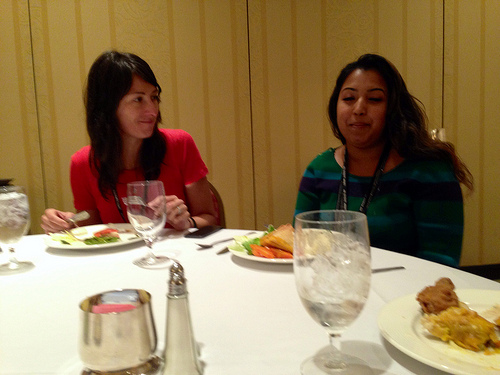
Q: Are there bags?
A: No, there are no bags.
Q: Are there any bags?
A: No, there are no bags.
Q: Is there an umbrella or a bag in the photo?
A: No, there are no bags or umbrellas.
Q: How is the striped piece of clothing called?
A: The clothing item is a blouse.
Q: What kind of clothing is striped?
A: The clothing is a blouse.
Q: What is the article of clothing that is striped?
A: The clothing item is a blouse.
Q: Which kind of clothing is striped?
A: The clothing is a blouse.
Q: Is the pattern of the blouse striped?
A: Yes, the blouse is striped.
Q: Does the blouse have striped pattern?
A: Yes, the blouse is striped.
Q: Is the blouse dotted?
A: No, the blouse is striped.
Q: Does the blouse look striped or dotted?
A: The blouse is striped.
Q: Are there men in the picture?
A: No, there are no men.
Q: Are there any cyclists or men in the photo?
A: No, there are no men or cyclists.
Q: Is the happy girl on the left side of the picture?
A: Yes, the girl is on the left of the image.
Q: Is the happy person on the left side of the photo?
A: Yes, the girl is on the left of the image.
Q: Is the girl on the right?
A: No, the girl is on the left of the image.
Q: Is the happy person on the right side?
A: No, the girl is on the left of the image.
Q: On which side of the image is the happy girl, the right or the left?
A: The girl is on the left of the image.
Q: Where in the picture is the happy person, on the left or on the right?
A: The girl is on the left of the image.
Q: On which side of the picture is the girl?
A: The girl is on the left of the image.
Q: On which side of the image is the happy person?
A: The girl is on the left of the image.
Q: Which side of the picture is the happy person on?
A: The girl is on the left of the image.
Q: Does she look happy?
A: Yes, the girl is happy.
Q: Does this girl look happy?
A: Yes, the girl is happy.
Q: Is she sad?
A: No, the girl is happy.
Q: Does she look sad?
A: No, the girl is happy.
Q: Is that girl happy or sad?
A: The girl is happy.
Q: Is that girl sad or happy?
A: The girl is happy.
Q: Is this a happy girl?
A: Yes, this is a happy girl.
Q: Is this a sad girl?
A: No, this is a happy girl.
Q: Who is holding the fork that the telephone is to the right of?
A: The girl is holding the fork.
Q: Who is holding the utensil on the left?
A: The girl is holding the fork.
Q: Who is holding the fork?
A: The girl is holding the fork.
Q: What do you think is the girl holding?
A: The girl is holding the fork.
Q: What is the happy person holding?
A: The girl is holding the fork.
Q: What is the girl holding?
A: The girl is holding the fork.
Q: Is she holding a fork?
A: Yes, the girl is holding a fork.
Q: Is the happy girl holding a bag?
A: No, the girl is holding a fork.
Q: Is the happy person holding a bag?
A: No, the girl is holding a fork.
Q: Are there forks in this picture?
A: Yes, there is a fork.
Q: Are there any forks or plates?
A: Yes, there is a fork.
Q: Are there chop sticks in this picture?
A: No, there are no chop sticks.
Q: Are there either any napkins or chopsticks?
A: No, there are no chopsticks or napkins.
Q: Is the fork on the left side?
A: Yes, the fork is on the left of the image.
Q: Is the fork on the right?
A: No, the fork is on the left of the image.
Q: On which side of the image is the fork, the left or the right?
A: The fork is on the left of the image.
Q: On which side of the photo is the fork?
A: The fork is on the left of the image.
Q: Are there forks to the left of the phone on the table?
A: Yes, there is a fork to the left of the phone.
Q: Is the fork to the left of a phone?
A: Yes, the fork is to the left of a phone.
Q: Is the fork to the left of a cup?
A: No, the fork is to the left of a phone.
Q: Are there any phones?
A: Yes, there is a phone.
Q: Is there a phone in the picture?
A: Yes, there is a phone.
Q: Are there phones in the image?
A: Yes, there is a phone.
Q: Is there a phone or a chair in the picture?
A: Yes, there is a phone.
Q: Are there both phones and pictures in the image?
A: No, there is a phone but no pictures.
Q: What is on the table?
A: The phone is on the table.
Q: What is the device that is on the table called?
A: The device is a phone.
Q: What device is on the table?
A: The device is a phone.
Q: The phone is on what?
A: The phone is on the table.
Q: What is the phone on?
A: The phone is on the table.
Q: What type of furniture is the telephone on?
A: The telephone is on the table.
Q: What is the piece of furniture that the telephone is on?
A: The piece of furniture is a table.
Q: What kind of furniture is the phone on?
A: The telephone is on the table.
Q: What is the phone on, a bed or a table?
A: The phone is on a table.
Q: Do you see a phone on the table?
A: Yes, there is a phone on the table.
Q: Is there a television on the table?
A: No, there is a phone on the table.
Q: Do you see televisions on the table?
A: No, there is a phone on the table.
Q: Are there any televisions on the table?
A: No, there is a phone on the table.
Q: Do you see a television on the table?
A: No, there is a phone on the table.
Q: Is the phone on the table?
A: Yes, the phone is on the table.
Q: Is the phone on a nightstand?
A: No, the phone is on the table.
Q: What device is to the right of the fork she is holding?
A: The device is a phone.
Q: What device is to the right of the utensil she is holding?
A: The device is a phone.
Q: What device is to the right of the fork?
A: The device is a phone.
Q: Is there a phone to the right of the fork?
A: Yes, there is a phone to the right of the fork.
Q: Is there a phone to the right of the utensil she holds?
A: Yes, there is a phone to the right of the fork.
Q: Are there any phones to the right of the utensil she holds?
A: Yes, there is a phone to the right of the fork.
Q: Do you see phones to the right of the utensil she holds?
A: Yes, there is a phone to the right of the fork.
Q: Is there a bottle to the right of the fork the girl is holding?
A: No, there is a phone to the right of the fork.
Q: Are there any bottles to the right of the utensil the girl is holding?
A: No, there is a phone to the right of the fork.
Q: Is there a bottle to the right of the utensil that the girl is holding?
A: No, there is a phone to the right of the fork.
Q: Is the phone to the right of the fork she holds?
A: Yes, the phone is to the right of the fork.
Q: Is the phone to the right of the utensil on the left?
A: Yes, the phone is to the right of the fork.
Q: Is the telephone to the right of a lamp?
A: No, the telephone is to the right of the fork.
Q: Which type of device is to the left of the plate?
A: The device is a phone.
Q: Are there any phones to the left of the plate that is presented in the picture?
A: Yes, there is a phone to the left of the plate.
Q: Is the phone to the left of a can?
A: No, the phone is to the left of a plate.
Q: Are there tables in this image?
A: Yes, there is a table.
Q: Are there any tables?
A: Yes, there is a table.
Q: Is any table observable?
A: Yes, there is a table.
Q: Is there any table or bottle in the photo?
A: Yes, there is a table.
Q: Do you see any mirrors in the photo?
A: No, there are no mirrors.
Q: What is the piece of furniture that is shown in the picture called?
A: The piece of furniture is a table.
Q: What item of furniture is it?
A: The piece of furniture is a table.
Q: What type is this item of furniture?
A: This is a table.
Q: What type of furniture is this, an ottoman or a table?
A: This is a table.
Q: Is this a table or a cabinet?
A: This is a table.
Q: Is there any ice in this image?
A: Yes, there is ice.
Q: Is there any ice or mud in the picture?
A: Yes, there is ice.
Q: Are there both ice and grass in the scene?
A: No, there is ice but no grass.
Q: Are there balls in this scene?
A: No, there are no balls.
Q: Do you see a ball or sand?
A: No, there are no balls or sand.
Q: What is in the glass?
A: The ice is in the glass.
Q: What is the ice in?
A: The ice is in the glass.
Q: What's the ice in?
A: The ice is in the glass.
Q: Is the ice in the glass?
A: Yes, the ice is in the glass.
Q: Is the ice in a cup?
A: No, the ice is in the glass.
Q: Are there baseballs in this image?
A: No, there are no baseballs.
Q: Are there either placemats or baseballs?
A: No, there are no baseballs or placemats.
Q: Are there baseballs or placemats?
A: No, there are no baseballs or placemats.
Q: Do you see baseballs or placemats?
A: No, there are no baseballs or placemats.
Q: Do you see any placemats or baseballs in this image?
A: No, there are no baseballs or placemats.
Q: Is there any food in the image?
A: Yes, there is food.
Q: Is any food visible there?
A: Yes, there is food.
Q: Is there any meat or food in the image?
A: Yes, there is food.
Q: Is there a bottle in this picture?
A: No, there are no bottles.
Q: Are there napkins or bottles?
A: No, there are no bottles or napkins.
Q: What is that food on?
A: The food is on the plate.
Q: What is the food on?
A: The food is on the plate.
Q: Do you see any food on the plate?
A: Yes, there is food on the plate.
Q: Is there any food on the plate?
A: Yes, there is food on the plate.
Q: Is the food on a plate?
A: Yes, the food is on a plate.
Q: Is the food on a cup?
A: No, the food is on a plate.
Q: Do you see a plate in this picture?
A: Yes, there is a plate.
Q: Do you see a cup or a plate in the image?
A: Yes, there is a plate.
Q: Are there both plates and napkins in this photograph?
A: No, there is a plate but no napkins.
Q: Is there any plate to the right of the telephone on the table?
A: Yes, there is a plate to the right of the phone.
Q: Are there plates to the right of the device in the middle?
A: Yes, there is a plate to the right of the phone.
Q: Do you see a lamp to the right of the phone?
A: No, there is a plate to the right of the phone.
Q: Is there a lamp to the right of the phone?
A: No, there is a plate to the right of the phone.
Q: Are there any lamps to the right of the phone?
A: No, there is a plate to the right of the phone.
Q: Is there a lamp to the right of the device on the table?
A: No, there is a plate to the right of the phone.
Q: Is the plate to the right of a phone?
A: Yes, the plate is to the right of a phone.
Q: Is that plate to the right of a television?
A: No, the plate is to the right of a phone.